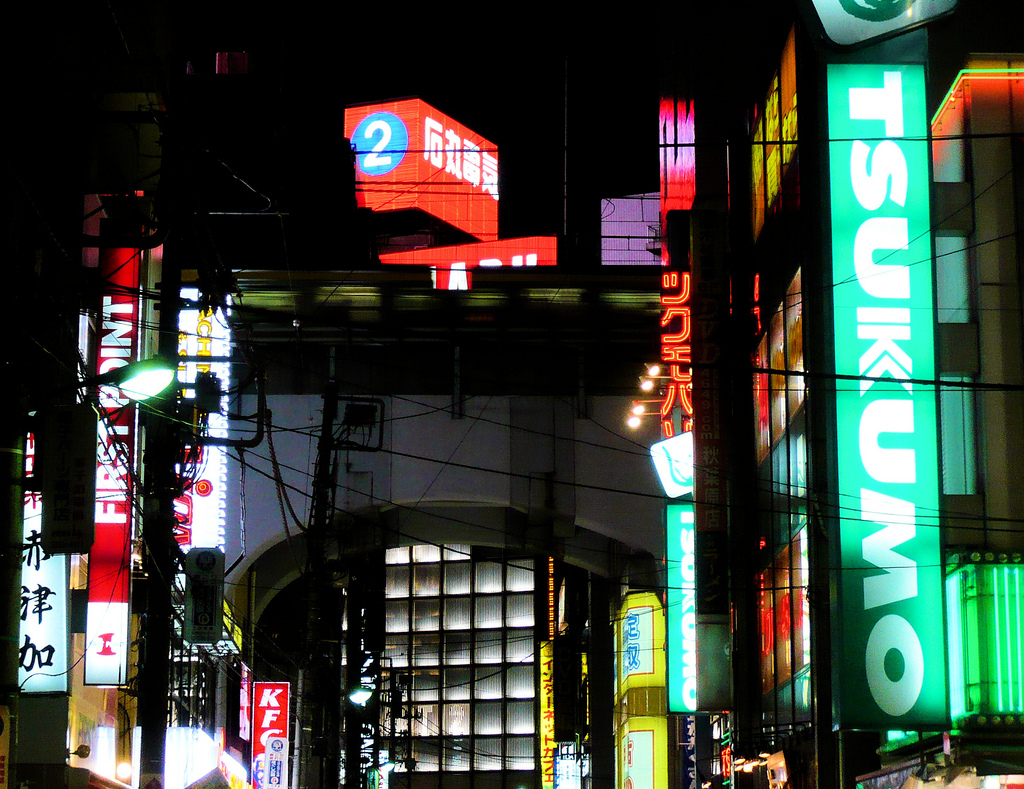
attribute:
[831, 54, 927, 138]
letter — T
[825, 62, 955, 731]
sign — blue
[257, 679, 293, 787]
sign — red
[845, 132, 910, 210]
letter — S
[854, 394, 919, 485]
letter — U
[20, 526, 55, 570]
letter — Chinese, black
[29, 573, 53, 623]
letter — Chinese, black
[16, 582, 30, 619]
letter — Chinese, black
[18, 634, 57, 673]
letter — Chinese, black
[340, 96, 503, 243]
advertisement — red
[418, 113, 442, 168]
letter — white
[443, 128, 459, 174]
letter — white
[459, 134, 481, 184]
letter — white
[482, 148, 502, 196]
letter — white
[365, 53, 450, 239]
circle — blue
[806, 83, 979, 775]
letters — white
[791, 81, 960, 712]
number — white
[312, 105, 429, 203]
ball — blue